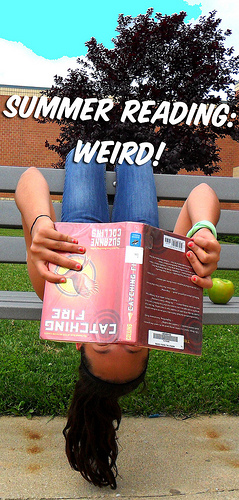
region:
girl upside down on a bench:
[6, 135, 224, 491]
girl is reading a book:
[17, 213, 215, 363]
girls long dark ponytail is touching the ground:
[59, 349, 158, 493]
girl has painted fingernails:
[31, 225, 218, 303]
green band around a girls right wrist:
[181, 218, 220, 255]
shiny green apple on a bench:
[207, 274, 233, 306]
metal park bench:
[0, 159, 237, 331]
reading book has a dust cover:
[32, 217, 210, 361]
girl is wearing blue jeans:
[58, 139, 161, 236]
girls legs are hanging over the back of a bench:
[2, 142, 238, 221]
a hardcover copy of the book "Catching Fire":
[44, 213, 202, 362]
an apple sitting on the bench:
[205, 275, 232, 300]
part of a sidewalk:
[1, 415, 237, 498]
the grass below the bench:
[2, 319, 237, 401]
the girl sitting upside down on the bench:
[13, 136, 221, 490]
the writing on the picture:
[8, 91, 236, 174]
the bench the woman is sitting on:
[0, 163, 235, 320]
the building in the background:
[2, 86, 237, 213]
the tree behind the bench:
[45, 11, 235, 179]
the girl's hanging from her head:
[55, 359, 131, 491]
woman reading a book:
[13, 139, 221, 486]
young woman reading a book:
[11, 140, 220, 488]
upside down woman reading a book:
[22, 138, 221, 488]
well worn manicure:
[50, 229, 86, 286]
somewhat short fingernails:
[54, 235, 86, 289]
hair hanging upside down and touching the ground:
[62, 349, 151, 487]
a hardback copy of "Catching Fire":
[39, 221, 213, 354]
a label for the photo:
[3, 93, 238, 165]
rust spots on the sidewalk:
[15, 423, 51, 481]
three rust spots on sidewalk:
[197, 426, 238, 471]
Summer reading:
[9, 72, 225, 172]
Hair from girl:
[52, 351, 161, 482]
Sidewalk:
[151, 457, 177, 469]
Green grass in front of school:
[174, 376, 200, 394]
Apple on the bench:
[204, 256, 238, 293]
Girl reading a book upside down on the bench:
[39, 151, 188, 300]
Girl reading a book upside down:
[46, 241, 214, 492]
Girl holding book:
[28, 215, 198, 354]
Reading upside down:
[20, 196, 197, 387]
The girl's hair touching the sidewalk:
[55, 451, 138, 489]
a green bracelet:
[184, 219, 217, 238]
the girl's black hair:
[57, 344, 153, 490]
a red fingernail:
[74, 262, 81, 270]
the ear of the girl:
[74, 339, 82, 349]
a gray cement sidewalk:
[0, 413, 236, 497]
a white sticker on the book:
[146, 326, 183, 349]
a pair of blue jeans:
[59, 143, 160, 230]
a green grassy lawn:
[0, 225, 238, 416]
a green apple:
[208, 276, 235, 306]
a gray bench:
[0, 164, 238, 327]